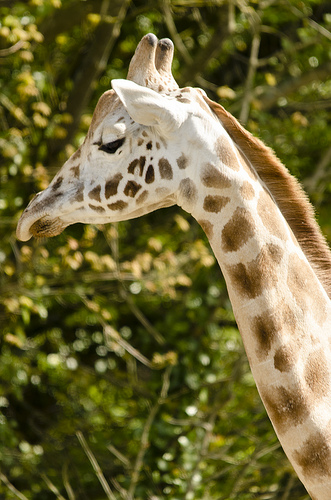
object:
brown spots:
[199, 158, 293, 299]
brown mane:
[201, 92, 331, 299]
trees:
[1, 0, 331, 499]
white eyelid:
[101, 121, 125, 146]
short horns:
[127, 32, 159, 82]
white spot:
[167, 104, 218, 166]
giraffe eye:
[98, 136, 126, 154]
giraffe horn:
[126, 32, 160, 91]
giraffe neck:
[203, 108, 330, 500]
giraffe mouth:
[15, 196, 60, 242]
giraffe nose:
[24, 191, 47, 212]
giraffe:
[16, 32, 331, 500]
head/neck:
[14, 30, 213, 245]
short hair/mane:
[203, 96, 331, 301]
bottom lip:
[29, 216, 65, 244]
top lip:
[16, 197, 43, 241]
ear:
[111, 79, 184, 132]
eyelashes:
[98, 136, 126, 153]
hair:
[204, 95, 331, 304]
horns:
[154, 38, 175, 76]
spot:
[274, 345, 299, 373]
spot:
[261, 346, 331, 424]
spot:
[202, 192, 231, 214]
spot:
[256, 193, 290, 243]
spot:
[239, 181, 255, 201]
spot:
[221, 206, 256, 254]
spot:
[52, 175, 64, 192]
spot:
[146, 140, 154, 151]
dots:
[101, 172, 177, 209]